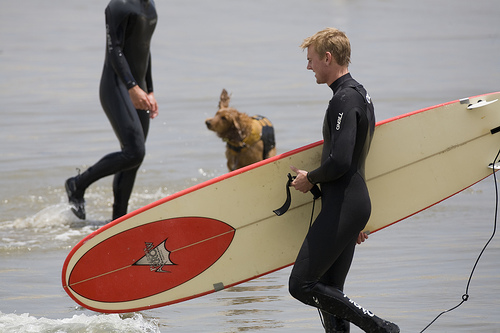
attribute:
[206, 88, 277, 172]
dog — brown, wet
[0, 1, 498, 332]
water — rippled, calm, white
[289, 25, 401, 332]
surfer — going to surf, male, walking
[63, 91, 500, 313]
surfboard — orange, creme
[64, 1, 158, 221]
surfer — female, a  woman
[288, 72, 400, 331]
wetsuit — black, long sleeved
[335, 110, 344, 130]
logo — white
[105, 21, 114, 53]
logo — white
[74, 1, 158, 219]
wetsuit — black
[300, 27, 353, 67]
hair — blond, blonde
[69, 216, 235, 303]
spot — red